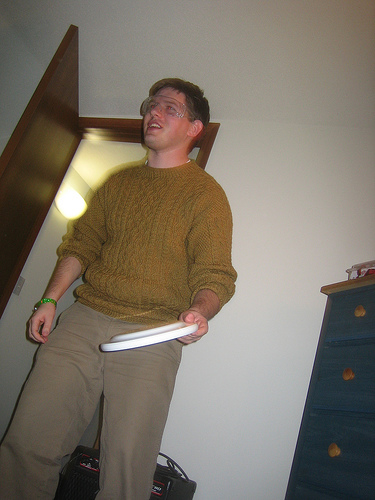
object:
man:
[0, 77, 238, 500]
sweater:
[58, 158, 238, 327]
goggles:
[140, 93, 199, 120]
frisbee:
[99, 319, 199, 352]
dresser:
[280, 275, 373, 500]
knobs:
[325, 441, 342, 457]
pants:
[2, 301, 187, 500]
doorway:
[0, 127, 199, 472]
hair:
[147, 74, 210, 150]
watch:
[31, 297, 58, 309]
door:
[0, 24, 80, 323]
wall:
[0, 0, 375, 500]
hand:
[175, 308, 209, 345]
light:
[55, 192, 88, 221]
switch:
[13, 274, 27, 298]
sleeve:
[186, 180, 238, 310]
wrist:
[36, 292, 59, 312]